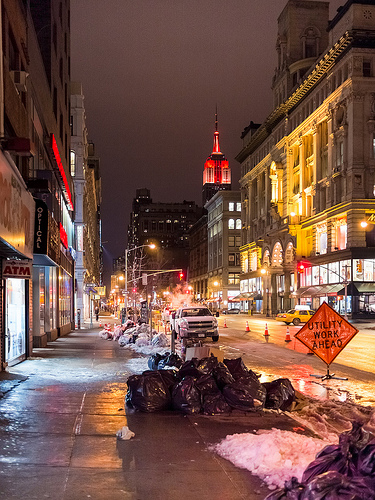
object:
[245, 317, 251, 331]
cone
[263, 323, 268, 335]
cone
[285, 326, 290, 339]
cone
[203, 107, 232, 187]
top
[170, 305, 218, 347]
truck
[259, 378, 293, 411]
trashbag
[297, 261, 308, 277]
red light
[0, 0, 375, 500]
city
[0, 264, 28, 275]
letters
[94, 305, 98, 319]
man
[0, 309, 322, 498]
sidewalk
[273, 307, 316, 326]
cab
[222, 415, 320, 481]
snow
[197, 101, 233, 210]
building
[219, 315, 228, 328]
cone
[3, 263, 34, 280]
sign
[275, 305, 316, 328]
taxi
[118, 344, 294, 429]
trash bags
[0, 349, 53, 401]
atm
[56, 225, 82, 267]
red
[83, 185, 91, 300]
up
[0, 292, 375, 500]
city street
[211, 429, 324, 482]
winter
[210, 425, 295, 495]
melted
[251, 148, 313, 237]
lighting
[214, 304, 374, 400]
street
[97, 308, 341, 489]
snow/ice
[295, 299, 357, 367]
sign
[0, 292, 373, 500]
road